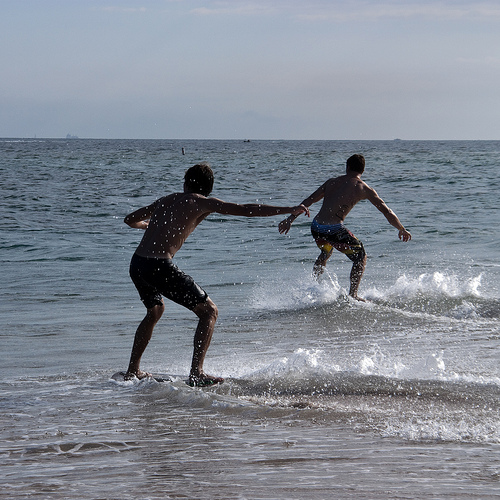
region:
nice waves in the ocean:
[241, 334, 473, 459]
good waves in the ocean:
[251, 325, 464, 448]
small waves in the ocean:
[247, 322, 462, 456]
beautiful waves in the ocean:
[258, 321, 458, 442]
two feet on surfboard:
[88, 350, 270, 411]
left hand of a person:
[270, 217, 304, 245]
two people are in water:
[86, 129, 456, 409]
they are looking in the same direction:
[93, 175, 418, 390]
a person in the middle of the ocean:
[151, 127, 211, 153]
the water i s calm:
[42, 139, 132, 252]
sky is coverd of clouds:
[231, 46, 326, 112]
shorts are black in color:
[125, 252, 199, 314]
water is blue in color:
[40, 210, 115, 288]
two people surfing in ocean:
[97, 148, 414, 384]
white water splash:
[251, 255, 335, 310]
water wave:
[253, 335, 498, 417]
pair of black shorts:
[116, 250, 216, 317]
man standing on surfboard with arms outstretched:
[101, 150, 312, 385]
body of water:
[5, 135, 496, 494]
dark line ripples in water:
[14, 189, 97, 234]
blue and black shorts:
[302, 210, 369, 268]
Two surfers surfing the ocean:
[105, 145, 416, 402]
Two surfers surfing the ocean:
[103, 148, 413, 395]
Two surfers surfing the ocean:
[113, 150, 416, 406]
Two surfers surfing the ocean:
[115, 148, 416, 395]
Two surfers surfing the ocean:
[110, 147, 415, 393]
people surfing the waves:
[74, 89, 433, 432]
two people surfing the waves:
[75, 126, 440, 416]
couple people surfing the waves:
[70, 93, 448, 406]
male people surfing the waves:
[83, 115, 450, 438]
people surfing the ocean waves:
[77, 108, 437, 433]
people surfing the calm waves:
[102, 104, 465, 455]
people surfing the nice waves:
[71, 122, 431, 407]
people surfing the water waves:
[47, 124, 451, 441]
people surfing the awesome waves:
[90, 101, 437, 417]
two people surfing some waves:
[87, 112, 456, 434]